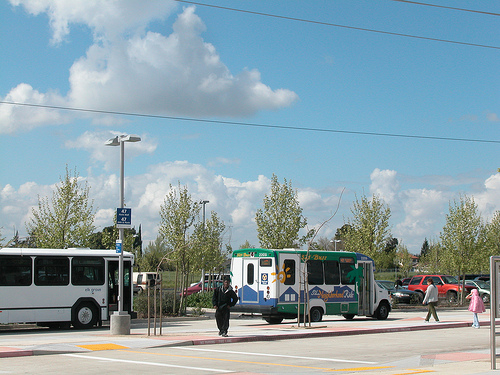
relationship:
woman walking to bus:
[422, 275, 443, 324] [226, 248, 393, 323]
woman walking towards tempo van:
[419, 275, 443, 324] [228, 247, 394, 324]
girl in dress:
[463, 283, 487, 331] [465, 276, 489, 335]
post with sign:
[118, 140, 125, 312] [114, 207, 131, 224]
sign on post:
[113, 204, 132, 231] [118, 141, 126, 309]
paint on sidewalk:
[78, 335, 123, 352] [1, 310, 498, 355]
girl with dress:
[463, 283, 487, 331] [466, 290, 486, 314]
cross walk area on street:
[119, 324, 319, 373] [328, 292, 479, 362]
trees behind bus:
[18, 164, 488, 310] [226, 248, 393, 323]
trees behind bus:
[18, 164, 488, 310] [0, 247, 137, 324]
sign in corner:
[489, 252, 499, 373] [418, 338, 499, 368]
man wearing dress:
[181, 254, 247, 342] [213, 284, 238, 329]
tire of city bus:
[72, 300, 97, 330] [0, 246, 138, 330]